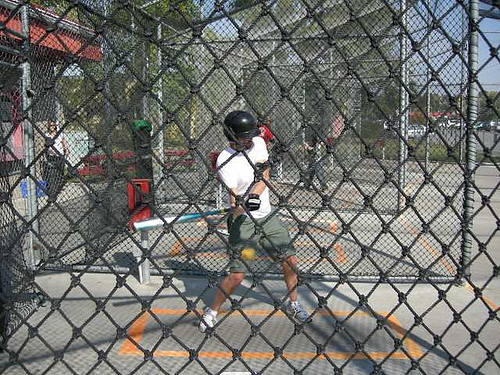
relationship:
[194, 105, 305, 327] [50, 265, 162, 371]
man in cage